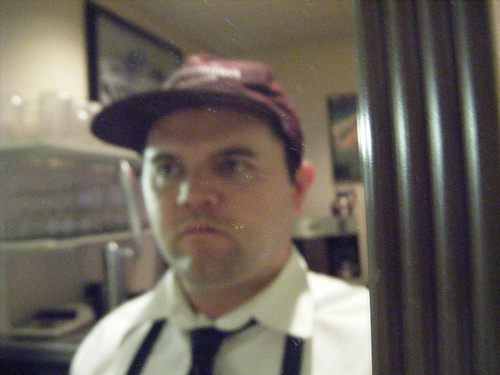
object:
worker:
[66, 49, 372, 374]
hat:
[88, 51, 305, 157]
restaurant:
[0, 2, 499, 375]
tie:
[181, 316, 256, 374]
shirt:
[66, 245, 373, 374]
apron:
[125, 319, 303, 374]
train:
[329, 114, 355, 152]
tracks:
[330, 145, 358, 164]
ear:
[290, 160, 315, 211]